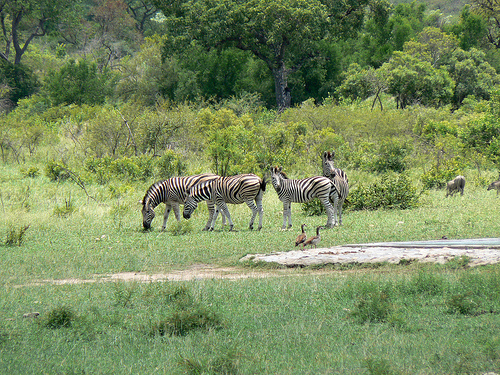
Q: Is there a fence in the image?
A: No, there are no fences.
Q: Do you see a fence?
A: No, there are no fences.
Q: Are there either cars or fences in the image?
A: No, there are no fences or cars.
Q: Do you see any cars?
A: No, there are no cars.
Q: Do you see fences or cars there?
A: No, there are no cars or fences.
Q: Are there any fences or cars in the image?
A: No, there are no cars or fences.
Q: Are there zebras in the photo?
A: Yes, there is a zebra.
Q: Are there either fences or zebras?
A: Yes, there is a zebra.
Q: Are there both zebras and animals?
A: Yes, there are both a zebra and an animal.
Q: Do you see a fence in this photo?
A: No, there are no fences.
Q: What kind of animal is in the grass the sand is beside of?
A: The animal is a zebra.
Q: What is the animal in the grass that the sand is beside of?
A: The animal is a zebra.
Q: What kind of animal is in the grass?
A: The animal is a zebra.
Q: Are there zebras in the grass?
A: Yes, there is a zebra in the grass.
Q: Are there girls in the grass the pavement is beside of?
A: No, there is a zebra in the grass.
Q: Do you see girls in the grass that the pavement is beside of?
A: No, there is a zebra in the grass.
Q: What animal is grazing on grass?
A: The zebra is grazing on grass.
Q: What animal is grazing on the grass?
A: The animal is a zebra.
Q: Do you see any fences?
A: No, there are no fences.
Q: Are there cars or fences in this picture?
A: No, there are no fences or cars.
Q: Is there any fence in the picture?
A: No, there are no fences.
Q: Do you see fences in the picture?
A: No, there are no fences.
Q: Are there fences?
A: No, there are no fences.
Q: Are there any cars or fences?
A: No, there are no fences or cars.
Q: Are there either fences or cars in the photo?
A: No, there are no fences or cars.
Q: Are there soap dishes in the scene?
A: No, there are no soap dishes.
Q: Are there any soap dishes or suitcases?
A: No, there are no soap dishes or suitcases.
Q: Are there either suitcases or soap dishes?
A: No, there are no soap dishes or suitcases.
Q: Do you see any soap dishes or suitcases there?
A: No, there are no soap dishes or suitcases.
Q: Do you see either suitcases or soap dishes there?
A: No, there are no soap dishes or suitcases.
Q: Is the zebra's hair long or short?
A: The hair is short.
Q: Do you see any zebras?
A: Yes, there is a zebra.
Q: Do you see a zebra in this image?
A: Yes, there is a zebra.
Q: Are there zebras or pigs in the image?
A: Yes, there is a zebra.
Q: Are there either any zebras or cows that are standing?
A: Yes, the zebra is standing.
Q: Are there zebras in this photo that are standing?
A: Yes, there is a zebra that is standing.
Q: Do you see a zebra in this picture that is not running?
A: Yes, there is a zebra that is standing .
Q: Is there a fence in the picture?
A: No, there are no fences.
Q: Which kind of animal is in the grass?
A: The animal is a zebra.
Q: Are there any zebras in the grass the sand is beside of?
A: Yes, there is a zebra in the grass.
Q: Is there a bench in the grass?
A: No, there is a zebra in the grass.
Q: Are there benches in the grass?
A: No, there is a zebra in the grass.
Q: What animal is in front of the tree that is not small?
A: The zebra is in front of the tree.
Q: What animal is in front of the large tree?
A: The animal is a zebra.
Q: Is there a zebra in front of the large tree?
A: Yes, there is a zebra in front of the tree.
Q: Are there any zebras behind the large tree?
A: No, the zebra is in front of the tree.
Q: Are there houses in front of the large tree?
A: No, there is a zebra in front of the tree.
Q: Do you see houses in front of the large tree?
A: No, there is a zebra in front of the tree.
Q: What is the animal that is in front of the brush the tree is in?
A: The animal is a zebra.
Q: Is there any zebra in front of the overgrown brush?
A: Yes, there is a zebra in front of the brush.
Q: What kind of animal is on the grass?
A: The animal is a zebra.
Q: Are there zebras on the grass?
A: Yes, there is a zebra on the grass.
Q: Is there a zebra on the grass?
A: Yes, there is a zebra on the grass.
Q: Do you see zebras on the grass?
A: Yes, there is a zebra on the grass.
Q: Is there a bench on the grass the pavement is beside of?
A: No, there is a zebra on the grass.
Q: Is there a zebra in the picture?
A: Yes, there is a zebra.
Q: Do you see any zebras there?
A: Yes, there is a zebra.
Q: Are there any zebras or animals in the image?
A: Yes, there is a zebra.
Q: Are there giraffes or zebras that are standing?
A: Yes, the zebra is standing.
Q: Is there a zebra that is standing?
A: Yes, there is a zebra that is standing.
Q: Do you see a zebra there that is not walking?
A: Yes, there is a zebra that is standing .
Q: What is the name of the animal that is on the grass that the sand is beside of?
A: The animal is a zebra.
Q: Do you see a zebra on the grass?
A: Yes, there is a zebra on the grass.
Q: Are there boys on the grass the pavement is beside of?
A: No, there is a zebra on the grass.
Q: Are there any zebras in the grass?
A: Yes, there is a zebra in the grass.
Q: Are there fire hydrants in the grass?
A: No, there is a zebra in the grass.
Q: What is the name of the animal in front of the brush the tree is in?
A: The animal is a zebra.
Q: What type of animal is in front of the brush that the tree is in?
A: The animal is a zebra.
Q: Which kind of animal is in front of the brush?
A: The animal is a zebra.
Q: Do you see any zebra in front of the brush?
A: Yes, there is a zebra in front of the brush.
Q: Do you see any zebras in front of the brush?
A: Yes, there is a zebra in front of the brush.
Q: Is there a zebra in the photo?
A: Yes, there is a zebra.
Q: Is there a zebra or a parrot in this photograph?
A: Yes, there is a zebra.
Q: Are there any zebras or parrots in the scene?
A: Yes, there is a zebra.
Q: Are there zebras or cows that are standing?
A: Yes, the zebra is standing.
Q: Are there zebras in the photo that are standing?
A: Yes, there is a zebra that is standing.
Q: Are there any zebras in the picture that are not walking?
A: Yes, there is a zebra that is standing.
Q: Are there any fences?
A: No, there are no fences.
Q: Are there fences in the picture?
A: No, there are no fences.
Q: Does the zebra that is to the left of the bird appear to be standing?
A: Yes, the zebra is standing.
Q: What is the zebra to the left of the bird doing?
A: The zebra is standing.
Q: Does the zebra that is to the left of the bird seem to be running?
A: No, the zebra is standing.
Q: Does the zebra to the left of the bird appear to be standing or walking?
A: The zebra is standing.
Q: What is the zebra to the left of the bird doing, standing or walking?
A: The zebra is standing.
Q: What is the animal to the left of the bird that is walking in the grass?
A: The animal is a zebra.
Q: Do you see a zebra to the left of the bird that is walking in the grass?
A: Yes, there is a zebra to the left of the bird.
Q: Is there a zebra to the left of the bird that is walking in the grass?
A: Yes, there is a zebra to the left of the bird.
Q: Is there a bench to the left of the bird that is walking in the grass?
A: No, there is a zebra to the left of the bird.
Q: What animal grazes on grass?
A: The zebra grazes on grass.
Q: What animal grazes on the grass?
A: The animal is a zebra.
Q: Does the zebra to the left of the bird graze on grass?
A: Yes, the zebra grazes on grass.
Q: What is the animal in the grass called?
A: The animal is a zebra.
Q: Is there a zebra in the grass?
A: Yes, there is a zebra in the grass.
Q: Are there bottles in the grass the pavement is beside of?
A: No, there is a zebra in the grass.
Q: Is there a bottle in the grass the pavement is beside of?
A: No, there is a zebra in the grass.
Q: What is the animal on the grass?
A: The animal is a zebra.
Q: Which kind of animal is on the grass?
A: The animal is a zebra.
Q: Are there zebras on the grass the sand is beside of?
A: Yes, there is a zebra on the grass.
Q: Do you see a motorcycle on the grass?
A: No, there is a zebra on the grass.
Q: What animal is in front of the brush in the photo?
A: The zebra is in front of the brush.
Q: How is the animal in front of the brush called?
A: The animal is a zebra.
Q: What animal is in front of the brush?
A: The animal is a zebra.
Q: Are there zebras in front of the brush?
A: Yes, there is a zebra in front of the brush.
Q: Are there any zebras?
A: Yes, there is a zebra.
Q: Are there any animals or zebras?
A: Yes, there is a zebra.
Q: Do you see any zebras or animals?
A: Yes, there is a zebra.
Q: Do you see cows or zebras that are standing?
A: Yes, the zebra is standing.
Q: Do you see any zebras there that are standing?
A: Yes, there is a zebra that is standing.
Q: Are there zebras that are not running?
A: Yes, there is a zebra that is standing.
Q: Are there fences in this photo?
A: No, there are no fences.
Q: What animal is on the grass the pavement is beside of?
A: The animal is a zebra.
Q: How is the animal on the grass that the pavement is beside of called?
A: The animal is a zebra.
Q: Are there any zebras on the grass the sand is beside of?
A: Yes, there is a zebra on the grass.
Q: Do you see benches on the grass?
A: No, there is a zebra on the grass.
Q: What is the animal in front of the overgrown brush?
A: The animal is a zebra.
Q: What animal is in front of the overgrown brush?
A: The animal is a zebra.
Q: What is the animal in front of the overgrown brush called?
A: The animal is a zebra.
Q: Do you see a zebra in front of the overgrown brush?
A: Yes, there is a zebra in front of the brush.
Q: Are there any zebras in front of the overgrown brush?
A: Yes, there is a zebra in front of the brush.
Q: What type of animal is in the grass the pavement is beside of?
A: The animal is a zebra.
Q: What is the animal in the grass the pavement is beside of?
A: The animal is a zebra.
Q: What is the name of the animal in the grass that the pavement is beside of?
A: The animal is a zebra.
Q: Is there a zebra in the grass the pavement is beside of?
A: Yes, there is a zebra in the grass.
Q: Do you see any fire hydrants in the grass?
A: No, there is a zebra in the grass.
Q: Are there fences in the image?
A: No, there are no fences.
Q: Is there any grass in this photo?
A: Yes, there is grass.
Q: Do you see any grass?
A: Yes, there is grass.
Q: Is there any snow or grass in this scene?
A: Yes, there is grass.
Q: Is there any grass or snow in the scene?
A: Yes, there is grass.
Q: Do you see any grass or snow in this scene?
A: Yes, there is grass.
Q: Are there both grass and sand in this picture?
A: Yes, there are both grass and sand.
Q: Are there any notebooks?
A: No, there are no notebooks.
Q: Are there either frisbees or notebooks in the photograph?
A: No, there are no notebooks or frisbees.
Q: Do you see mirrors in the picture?
A: No, there are no mirrors.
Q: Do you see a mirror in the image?
A: No, there are no mirrors.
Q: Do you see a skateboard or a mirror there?
A: No, there are no mirrors or skateboards.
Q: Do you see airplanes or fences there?
A: No, there are no fences or airplanes.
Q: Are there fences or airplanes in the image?
A: No, there are no fences or airplanes.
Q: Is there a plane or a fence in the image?
A: No, there are no fences or airplanes.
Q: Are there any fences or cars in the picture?
A: No, there are no fences or cars.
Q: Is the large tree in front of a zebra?
A: No, the tree is behind a zebra.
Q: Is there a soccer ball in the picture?
A: No, there are no soccer balls.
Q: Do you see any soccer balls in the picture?
A: No, there are no soccer balls.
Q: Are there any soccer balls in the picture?
A: No, there are no soccer balls.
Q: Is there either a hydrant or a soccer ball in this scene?
A: No, there are no soccer balls or fire hydrants.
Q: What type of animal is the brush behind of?
A: The brush is behind the zebra.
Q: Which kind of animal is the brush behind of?
A: The brush is behind the zebra.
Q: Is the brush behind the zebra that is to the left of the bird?
A: Yes, the brush is behind the zebra.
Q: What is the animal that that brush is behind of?
A: The animal is a zebra.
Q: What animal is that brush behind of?
A: The brush is behind the zebra.